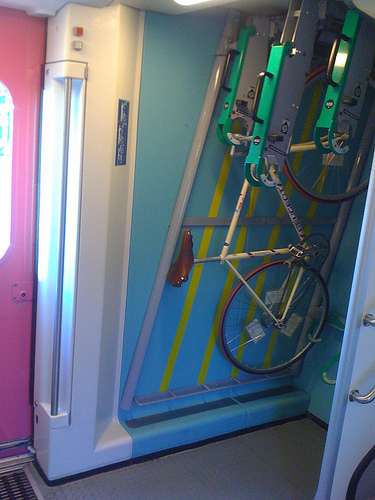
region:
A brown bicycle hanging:
[157, 63, 348, 435]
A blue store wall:
[159, 46, 199, 141]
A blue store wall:
[137, 161, 167, 253]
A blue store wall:
[297, 371, 330, 408]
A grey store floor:
[180, 440, 228, 483]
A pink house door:
[3, 315, 28, 455]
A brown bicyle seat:
[164, 214, 198, 282]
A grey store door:
[338, 403, 373, 459]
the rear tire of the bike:
[219, 257, 326, 374]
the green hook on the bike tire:
[302, 313, 330, 348]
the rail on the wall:
[349, 368, 373, 406]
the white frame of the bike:
[218, 190, 310, 329]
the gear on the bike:
[296, 232, 329, 273]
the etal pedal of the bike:
[287, 241, 310, 259]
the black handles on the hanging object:
[212, 34, 348, 129]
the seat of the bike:
[167, 223, 195, 289]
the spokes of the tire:
[306, 160, 365, 190]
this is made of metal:
[152, 211, 190, 280]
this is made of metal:
[208, 21, 257, 144]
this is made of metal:
[310, 9, 357, 144]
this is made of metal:
[229, 73, 261, 163]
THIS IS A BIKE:
[170, 58, 371, 385]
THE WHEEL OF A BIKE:
[208, 260, 328, 376]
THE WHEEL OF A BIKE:
[268, 56, 374, 204]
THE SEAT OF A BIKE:
[153, 223, 212, 293]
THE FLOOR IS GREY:
[197, 452, 272, 498]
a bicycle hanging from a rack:
[167, 29, 370, 375]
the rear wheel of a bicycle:
[216, 260, 331, 375]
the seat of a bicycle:
[165, 225, 193, 288]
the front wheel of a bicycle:
[287, 66, 370, 199]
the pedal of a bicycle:
[286, 240, 308, 263]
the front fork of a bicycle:
[285, 134, 351, 155]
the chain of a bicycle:
[275, 261, 311, 330]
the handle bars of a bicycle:
[228, 130, 282, 143]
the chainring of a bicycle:
[298, 230, 328, 272]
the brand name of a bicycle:
[275, 179, 305, 237]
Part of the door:
[9, 322, 24, 357]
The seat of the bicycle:
[164, 227, 198, 289]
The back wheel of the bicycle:
[214, 256, 338, 379]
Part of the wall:
[165, 99, 192, 120]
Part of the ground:
[199, 465, 233, 482]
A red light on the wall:
[70, 21, 85, 36]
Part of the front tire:
[305, 183, 327, 202]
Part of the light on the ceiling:
[176, 0, 191, 3]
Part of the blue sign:
[118, 123, 125, 133]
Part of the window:
[1, 186, 7, 209]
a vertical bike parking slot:
[162, 33, 374, 388]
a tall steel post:
[44, 63, 74, 412]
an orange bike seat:
[159, 223, 196, 291]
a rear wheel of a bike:
[211, 254, 326, 379]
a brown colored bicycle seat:
[159, 218, 210, 297]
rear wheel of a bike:
[214, 253, 329, 389]